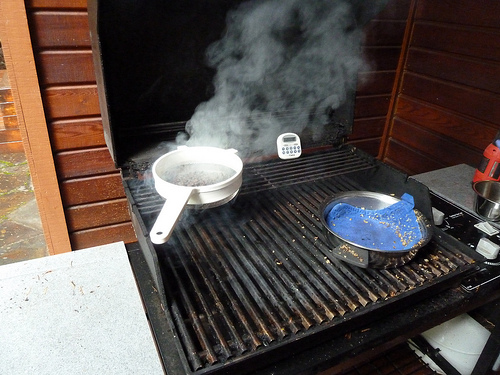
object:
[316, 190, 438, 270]
bowl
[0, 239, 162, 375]
board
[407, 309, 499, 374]
container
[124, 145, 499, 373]
grill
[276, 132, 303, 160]
timer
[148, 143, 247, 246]
bowl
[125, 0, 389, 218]
smoke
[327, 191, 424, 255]
blue item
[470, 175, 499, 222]
silver bowl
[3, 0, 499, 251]
building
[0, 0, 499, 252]
wall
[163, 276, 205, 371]
metal rail